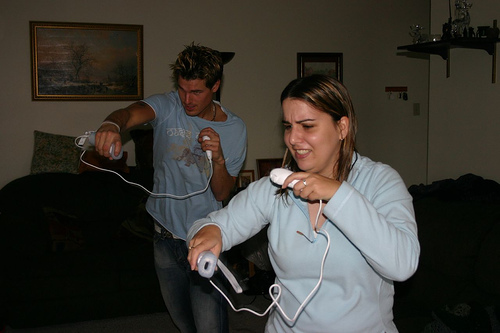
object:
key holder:
[379, 80, 414, 106]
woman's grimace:
[281, 115, 325, 168]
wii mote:
[185, 166, 330, 321]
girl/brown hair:
[272, 74, 357, 206]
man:
[91, 33, 254, 333]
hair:
[171, 41, 225, 88]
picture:
[297, 50, 347, 83]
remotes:
[182, 126, 226, 189]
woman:
[185, 73, 421, 331]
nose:
[289, 123, 302, 144]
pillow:
[24, 134, 124, 192]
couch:
[0, 168, 198, 325]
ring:
[186, 246, 193, 248]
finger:
[188, 237, 193, 261]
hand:
[277, 167, 329, 208]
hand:
[192, 121, 222, 159]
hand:
[185, 220, 222, 272]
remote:
[185, 245, 220, 279]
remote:
[74, 127, 129, 164]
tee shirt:
[137, 90, 254, 249]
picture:
[35, 24, 146, 97]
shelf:
[392, 1, 496, 82]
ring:
[300, 181, 309, 185]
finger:
[293, 180, 306, 194]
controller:
[90, 41, 249, 282]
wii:
[71, 123, 138, 180]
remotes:
[268, 163, 305, 192]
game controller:
[197, 167, 330, 324]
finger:
[281, 172, 309, 189]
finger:
[113, 135, 123, 153]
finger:
[196, 129, 218, 138]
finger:
[94, 131, 100, 152]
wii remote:
[188, 240, 240, 304]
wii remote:
[74, 126, 136, 178]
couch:
[413, 172, 500, 305]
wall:
[430, 67, 484, 165]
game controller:
[66, 118, 224, 198]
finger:
[190, 236, 217, 271]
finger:
[305, 190, 321, 205]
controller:
[185, 71, 421, 282]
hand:
[87, 111, 125, 160]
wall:
[235, 3, 293, 67]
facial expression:
[284, 100, 334, 169]